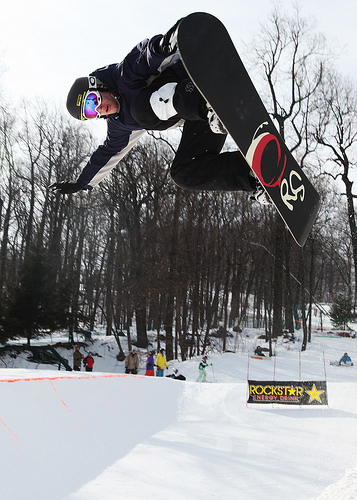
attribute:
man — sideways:
[46, 16, 272, 206]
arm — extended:
[46, 120, 147, 195]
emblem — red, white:
[244, 120, 287, 188]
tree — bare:
[305, 62, 345, 264]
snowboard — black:
[150, 3, 338, 270]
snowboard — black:
[163, 2, 332, 256]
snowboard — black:
[158, 5, 344, 279]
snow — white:
[16, 333, 350, 427]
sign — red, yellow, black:
[244, 377, 330, 409]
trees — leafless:
[18, 95, 93, 336]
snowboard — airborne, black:
[170, 7, 325, 249]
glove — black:
[44, 176, 93, 200]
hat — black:
[64, 74, 87, 123]